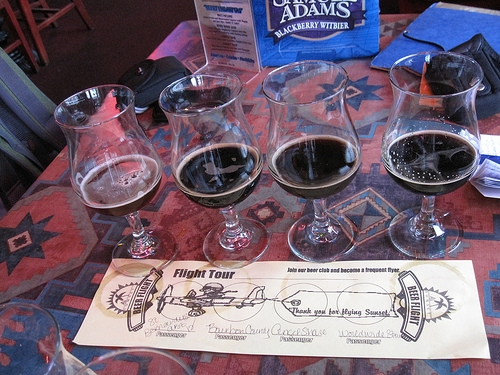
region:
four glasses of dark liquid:
[55, 51, 482, 277]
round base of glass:
[386, 203, 464, 260]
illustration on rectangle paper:
[70, 258, 490, 360]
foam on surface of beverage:
[82, 153, 157, 206]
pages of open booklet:
[469, 133, 496, 197]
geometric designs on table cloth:
[3, 13, 497, 373]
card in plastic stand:
[191, 1, 262, 86]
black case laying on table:
[119, 55, 189, 114]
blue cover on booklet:
[374, 7, 498, 74]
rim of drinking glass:
[0, 297, 62, 372]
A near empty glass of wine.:
[51, 83, 179, 282]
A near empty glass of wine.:
[155, 68, 271, 271]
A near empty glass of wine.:
[255, 58, 358, 265]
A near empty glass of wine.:
[379, 50, 485, 259]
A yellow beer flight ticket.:
[71, 258, 493, 363]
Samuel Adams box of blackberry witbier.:
[189, 0, 381, 74]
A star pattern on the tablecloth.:
[0, 210, 65, 277]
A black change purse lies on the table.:
[420, 32, 497, 126]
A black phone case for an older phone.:
[114, 53, 189, 115]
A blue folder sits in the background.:
[362, 0, 499, 77]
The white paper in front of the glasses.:
[79, 250, 484, 355]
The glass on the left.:
[60, 80, 177, 282]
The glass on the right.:
[382, 55, 487, 253]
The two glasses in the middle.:
[157, 58, 361, 263]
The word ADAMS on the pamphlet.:
[270, 1, 360, 13]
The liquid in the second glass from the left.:
[179, 144, 257, 204]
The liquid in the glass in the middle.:
[276, 141, 356, 192]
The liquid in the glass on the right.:
[383, 133, 475, 187]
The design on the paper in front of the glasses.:
[107, 268, 455, 350]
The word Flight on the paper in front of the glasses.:
[165, 263, 210, 280]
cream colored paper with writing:
[70, 255, 491, 361]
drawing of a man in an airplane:
[153, 281, 300, 314]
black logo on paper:
[394, 265, 455, 343]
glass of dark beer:
[376, 45, 483, 256]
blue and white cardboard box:
[190, 0, 380, 70]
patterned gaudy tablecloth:
[0, 17, 498, 373]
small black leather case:
[113, 50, 190, 114]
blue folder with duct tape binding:
[370, 3, 497, 73]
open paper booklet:
[472, 126, 499, 198]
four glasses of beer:
[50, 50, 482, 277]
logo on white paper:
[107, 267, 187, 332]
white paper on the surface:
[333, 245, 483, 339]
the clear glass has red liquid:
[377, 45, 483, 259]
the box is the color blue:
[251, 3, 385, 68]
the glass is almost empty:
[54, 88, 179, 282]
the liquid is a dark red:
[273, 133, 365, 198]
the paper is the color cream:
[76, 257, 488, 366]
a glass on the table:
[57, 86, 192, 271]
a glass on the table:
[149, 68, 269, 266]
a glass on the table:
[266, 58, 365, 261]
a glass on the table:
[380, 65, 498, 204]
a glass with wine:
[61, 101, 173, 266]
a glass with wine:
[156, 78, 261, 282]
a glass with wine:
[261, 52, 356, 257]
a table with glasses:
[201, 173, 460, 364]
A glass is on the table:
[37, 70, 185, 291]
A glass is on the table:
[252, 46, 377, 267]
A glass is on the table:
[375, 35, 491, 289]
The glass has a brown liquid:
[371, 38, 493, 267]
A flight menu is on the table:
[55, 235, 498, 359]